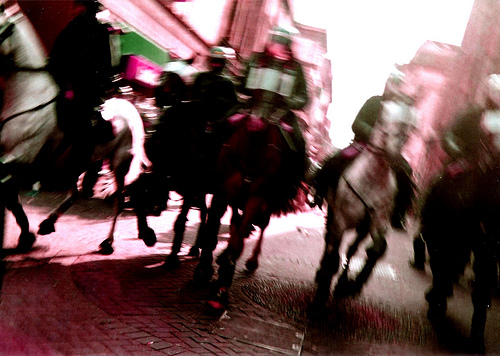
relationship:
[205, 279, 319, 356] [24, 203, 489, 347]
blocks on ground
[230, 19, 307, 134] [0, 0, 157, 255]
man on horse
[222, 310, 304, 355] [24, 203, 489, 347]
square on ground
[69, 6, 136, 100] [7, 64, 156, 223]
rider on horse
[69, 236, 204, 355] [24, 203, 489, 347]
circle on ground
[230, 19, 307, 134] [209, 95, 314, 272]
man on horse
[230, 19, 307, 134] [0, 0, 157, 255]
man riding horse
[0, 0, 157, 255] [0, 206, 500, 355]
horse on road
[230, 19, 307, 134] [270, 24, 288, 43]
man with hat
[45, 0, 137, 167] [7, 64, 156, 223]
rider riding horse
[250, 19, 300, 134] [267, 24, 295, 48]
man wearing hat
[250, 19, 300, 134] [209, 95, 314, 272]
man on horse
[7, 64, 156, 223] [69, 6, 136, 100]
horse with rider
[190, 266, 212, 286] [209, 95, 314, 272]
hoof of horse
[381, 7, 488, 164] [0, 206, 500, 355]
buildings on road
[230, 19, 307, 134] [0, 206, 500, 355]
man in road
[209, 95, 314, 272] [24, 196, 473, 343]
horse galloping on road